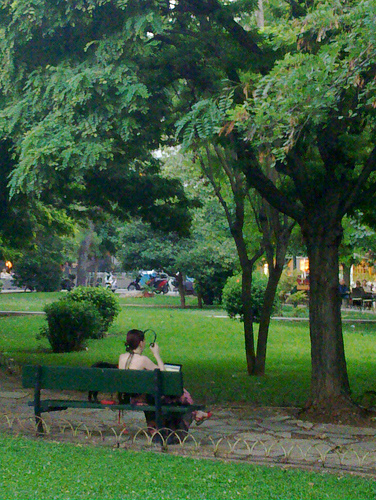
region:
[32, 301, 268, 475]
a woman sitting on a bench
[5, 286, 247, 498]
a woman sitting on a wooden bench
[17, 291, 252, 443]
a woman sitting on a green wooden bench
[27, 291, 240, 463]
a woman sitting on a green bench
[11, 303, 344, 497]
a woman sitting in a park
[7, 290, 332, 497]
a bench in a park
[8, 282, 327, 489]
a wooden bench in a park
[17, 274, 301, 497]
a green bench in a park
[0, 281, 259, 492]
a bench on a sidewalk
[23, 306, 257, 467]
a green bench on a sidewalk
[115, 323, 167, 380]
A woman putting on head phones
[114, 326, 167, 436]
A woman sitting on a green bench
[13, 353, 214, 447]
A green wooden park bench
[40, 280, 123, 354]
Two large bushes in a field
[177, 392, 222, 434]
A woman wearing red sandals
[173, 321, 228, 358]
A green grassy field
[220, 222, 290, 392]
A tree without many leaves in a park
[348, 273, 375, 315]
People sitting together in chairs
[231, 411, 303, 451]
A grey stone walk way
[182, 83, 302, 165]
Green and brown leaves on a tree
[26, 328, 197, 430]
woman sitting on park bench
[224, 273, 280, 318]
green leaves on bush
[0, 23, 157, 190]
leaves hanging from branch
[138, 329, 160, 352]
head phones in woman's hand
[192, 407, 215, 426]
red shoe on foot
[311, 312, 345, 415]
bark on tree truck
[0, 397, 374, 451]
stone walkway of park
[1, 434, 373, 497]
green grass in foreground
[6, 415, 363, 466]
short fence along walkway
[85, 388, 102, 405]
back legs of animal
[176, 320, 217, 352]
the grass is short and green.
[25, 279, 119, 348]
two dark green bushes.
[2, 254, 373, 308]
A street scene behind trees and bushes.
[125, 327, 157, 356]
The woman is holding earphones.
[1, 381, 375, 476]
A stone walkway with different size stones.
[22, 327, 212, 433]
The woman is sitting on a wooden bench.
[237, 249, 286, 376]
A tree has three forks.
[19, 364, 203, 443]
The wooden bench is green.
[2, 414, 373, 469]
The edging is shaped like arches.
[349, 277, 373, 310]
Two people are sitting facing each other.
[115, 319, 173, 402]
woman sitting on bench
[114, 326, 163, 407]
woman sitting on green bench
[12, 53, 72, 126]
green leaves on brown tree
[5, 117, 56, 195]
green leaves on brown tree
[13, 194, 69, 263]
green leaves on brown tree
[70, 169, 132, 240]
green leaves on brown tree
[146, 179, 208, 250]
green leaves on brown tree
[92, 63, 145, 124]
green leaves on brown tree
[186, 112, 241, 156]
green leaves on brown tree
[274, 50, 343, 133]
green leaves on brown tree